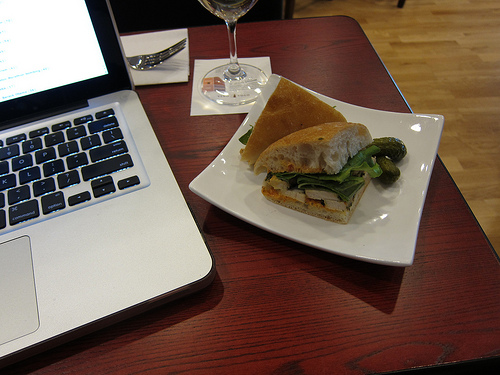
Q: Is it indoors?
A: Yes, it is indoors.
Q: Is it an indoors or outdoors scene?
A: It is indoors.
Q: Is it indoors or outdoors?
A: It is indoors.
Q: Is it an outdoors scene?
A: No, it is indoors.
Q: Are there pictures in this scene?
A: No, there are no pictures.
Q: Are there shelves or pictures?
A: No, there are no pictures or shelves.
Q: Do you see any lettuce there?
A: Yes, there is lettuce.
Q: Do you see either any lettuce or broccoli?
A: Yes, there is lettuce.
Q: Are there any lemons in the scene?
A: No, there are no lemons.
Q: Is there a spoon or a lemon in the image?
A: No, there are no lemons or spoons.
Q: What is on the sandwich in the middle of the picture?
A: The lettuce is on the sandwich.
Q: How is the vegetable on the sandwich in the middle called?
A: The vegetable is lettuce.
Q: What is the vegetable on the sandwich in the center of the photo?
A: The vegetable is lettuce.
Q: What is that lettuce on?
A: The lettuce is on the sandwich.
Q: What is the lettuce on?
A: The lettuce is on the sandwich.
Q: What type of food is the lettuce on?
A: The lettuce is on the sandwich.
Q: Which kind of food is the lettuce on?
A: The lettuce is on the sandwich.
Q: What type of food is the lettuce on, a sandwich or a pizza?
A: The lettuce is on a sandwich.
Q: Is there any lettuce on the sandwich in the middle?
A: Yes, there is lettuce on the sandwich.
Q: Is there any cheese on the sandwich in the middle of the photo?
A: No, there is lettuce on the sandwich.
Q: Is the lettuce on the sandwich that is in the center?
A: Yes, the lettuce is on the sandwich.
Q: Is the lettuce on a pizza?
A: No, the lettuce is on the sandwich.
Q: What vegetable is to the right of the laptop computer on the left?
A: The vegetable is lettuce.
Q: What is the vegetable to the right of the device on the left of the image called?
A: The vegetable is lettuce.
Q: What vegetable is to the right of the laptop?
A: The vegetable is lettuce.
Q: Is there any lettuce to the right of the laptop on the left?
A: Yes, there is lettuce to the right of the laptop.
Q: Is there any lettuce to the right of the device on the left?
A: Yes, there is lettuce to the right of the laptop.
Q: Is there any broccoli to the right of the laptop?
A: No, there is lettuce to the right of the laptop.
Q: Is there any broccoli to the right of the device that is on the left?
A: No, there is lettuce to the right of the laptop.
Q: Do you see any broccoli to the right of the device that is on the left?
A: No, there is lettuce to the right of the laptop.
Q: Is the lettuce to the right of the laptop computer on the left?
A: Yes, the lettuce is to the right of the laptop.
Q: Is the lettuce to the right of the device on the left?
A: Yes, the lettuce is to the right of the laptop.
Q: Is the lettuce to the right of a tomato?
A: No, the lettuce is to the right of the laptop.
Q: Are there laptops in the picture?
A: Yes, there is a laptop.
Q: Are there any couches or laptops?
A: Yes, there is a laptop.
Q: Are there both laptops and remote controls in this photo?
A: No, there is a laptop but no remote controls.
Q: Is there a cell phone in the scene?
A: No, there are no cell phones.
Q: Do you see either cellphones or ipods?
A: No, there are no cellphones or ipods.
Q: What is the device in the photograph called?
A: The device is a laptop.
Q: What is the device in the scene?
A: The device is a laptop.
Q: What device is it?
A: The device is a laptop.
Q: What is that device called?
A: This is a laptop.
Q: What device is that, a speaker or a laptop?
A: This is a laptop.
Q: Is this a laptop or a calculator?
A: This is a laptop.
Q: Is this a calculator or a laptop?
A: This is a laptop.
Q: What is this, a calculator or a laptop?
A: This is a laptop.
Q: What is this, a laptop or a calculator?
A: This is a laptop.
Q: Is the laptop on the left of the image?
A: Yes, the laptop is on the left of the image.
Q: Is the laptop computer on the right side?
A: No, the laptop computer is on the left of the image.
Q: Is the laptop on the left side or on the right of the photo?
A: The laptop is on the left of the image.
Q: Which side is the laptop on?
A: The laptop is on the left of the image.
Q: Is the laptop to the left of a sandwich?
A: Yes, the laptop is to the left of a sandwich.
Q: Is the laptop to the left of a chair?
A: No, the laptop is to the left of a sandwich.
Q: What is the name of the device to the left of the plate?
A: The device is a laptop.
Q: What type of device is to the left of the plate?
A: The device is a laptop.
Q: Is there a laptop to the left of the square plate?
A: Yes, there is a laptop to the left of the plate.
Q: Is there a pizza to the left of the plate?
A: No, there is a laptop to the left of the plate.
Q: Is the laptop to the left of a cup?
A: No, the laptop is to the left of the plate.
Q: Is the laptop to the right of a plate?
A: No, the laptop is to the left of a plate.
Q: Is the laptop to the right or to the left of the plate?
A: The laptop is to the left of the plate.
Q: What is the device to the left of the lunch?
A: The device is a laptop.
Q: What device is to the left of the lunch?
A: The device is a laptop.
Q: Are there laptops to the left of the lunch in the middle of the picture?
A: Yes, there is a laptop to the left of the lunch.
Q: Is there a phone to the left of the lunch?
A: No, there is a laptop to the left of the lunch.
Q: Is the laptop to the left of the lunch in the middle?
A: Yes, the laptop is to the left of the lunch.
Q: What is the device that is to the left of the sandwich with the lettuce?
A: The device is a laptop.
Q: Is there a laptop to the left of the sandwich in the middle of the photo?
A: Yes, there is a laptop to the left of the sandwich.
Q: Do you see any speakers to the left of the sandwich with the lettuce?
A: No, there is a laptop to the left of the sandwich.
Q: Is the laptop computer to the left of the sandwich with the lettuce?
A: Yes, the laptop computer is to the left of the sandwich.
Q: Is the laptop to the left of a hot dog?
A: No, the laptop is to the left of the sandwich.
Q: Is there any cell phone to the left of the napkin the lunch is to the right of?
A: No, there is a laptop to the left of the napkin.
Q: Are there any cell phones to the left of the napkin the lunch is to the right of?
A: No, there is a laptop to the left of the napkin.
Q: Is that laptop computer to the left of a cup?
A: No, the laptop computer is to the left of the napkin.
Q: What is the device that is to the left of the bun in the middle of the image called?
A: The device is a laptop.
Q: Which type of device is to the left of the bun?
A: The device is a laptop.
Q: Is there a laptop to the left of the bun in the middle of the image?
A: Yes, there is a laptop to the left of the bun.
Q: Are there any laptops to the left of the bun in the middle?
A: Yes, there is a laptop to the left of the bun.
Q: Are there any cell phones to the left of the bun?
A: No, there is a laptop to the left of the bun.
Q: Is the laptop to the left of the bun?
A: Yes, the laptop is to the left of the bun.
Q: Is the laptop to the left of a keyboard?
A: No, the laptop is to the left of the bun.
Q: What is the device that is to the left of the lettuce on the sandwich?
A: The device is a laptop.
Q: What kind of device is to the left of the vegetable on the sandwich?
A: The device is a laptop.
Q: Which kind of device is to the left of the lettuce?
A: The device is a laptop.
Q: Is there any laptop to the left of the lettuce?
A: Yes, there is a laptop to the left of the lettuce.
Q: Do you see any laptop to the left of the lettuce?
A: Yes, there is a laptop to the left of the lettuce.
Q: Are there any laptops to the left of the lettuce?
A: Yes, there is a laptop to the left of the lettuce.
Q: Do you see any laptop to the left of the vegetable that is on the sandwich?
A: Yes, there is a laptop to the left of the lettuce.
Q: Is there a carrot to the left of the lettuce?
A: No, there is a laptop to the left of the lettuce.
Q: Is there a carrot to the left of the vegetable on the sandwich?
A: No, there is a laptop to the left of the lettuce.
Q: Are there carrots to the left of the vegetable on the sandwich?
A: No, there is a laptop to the left of the lettuce.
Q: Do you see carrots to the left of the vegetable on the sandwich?
A: No, there is a laptop to the left of the lettuce.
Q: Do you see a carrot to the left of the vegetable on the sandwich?
A: No, there is a laptop to the left of the lettuce.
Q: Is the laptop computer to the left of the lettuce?
A: Yes, the laptop computer is to the left of the lettuce.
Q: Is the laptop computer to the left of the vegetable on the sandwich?
A: Yes, the laptop computer is to the left of the lettuce.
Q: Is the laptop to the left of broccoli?
A: No, the laptop is to the left of the lettuce.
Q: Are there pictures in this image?
A: No, there are no pictures.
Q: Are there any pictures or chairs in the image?
A: No, there are no pictures or chairs.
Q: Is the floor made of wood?
A: Yes, the floor is made of wood.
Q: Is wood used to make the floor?
A: Yes, the floor is made of wood.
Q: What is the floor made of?
A: The floor is made of wood.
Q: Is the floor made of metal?
A: No, the floor is made of wood.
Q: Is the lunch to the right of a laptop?
A: Yes, the lunch is to the right of a laptop.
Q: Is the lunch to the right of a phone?
A: No, the lunch is to the right of a laptop.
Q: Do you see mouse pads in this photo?
A: Yes, there is a mouse pad.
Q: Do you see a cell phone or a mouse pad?
A: Yes, there is a mouse pad.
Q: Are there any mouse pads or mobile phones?
A: Yes, there is a mouse pad.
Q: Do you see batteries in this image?
A: No, there are no batteries.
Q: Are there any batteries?
A: No, there are no batteries.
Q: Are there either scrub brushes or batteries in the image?
A: No, there are no batteries or scrub brushes.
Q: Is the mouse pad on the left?
A: Yes, the mouse pad is on the left of the image.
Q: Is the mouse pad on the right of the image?
A: No, the mouse pad is on the left of the image.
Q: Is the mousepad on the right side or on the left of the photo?
A: The mousepad is on the left of the image.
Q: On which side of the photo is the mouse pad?
A: The mouse pad is on the left of the image.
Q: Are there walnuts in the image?
A: No, there are no walnuts.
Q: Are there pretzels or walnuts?
A: No, there are no walnuts or pretzels.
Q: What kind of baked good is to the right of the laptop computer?
A: The food is a bun.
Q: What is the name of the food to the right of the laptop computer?
A: The food is a bun.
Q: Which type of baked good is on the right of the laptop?
A: The food is a bun.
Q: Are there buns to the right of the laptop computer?
A: Yes, there is a bun to the right of the laptop computer.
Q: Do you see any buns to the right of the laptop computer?
A: Yes, there is a bun to the right of the laptop computer.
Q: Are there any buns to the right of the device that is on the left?
A: Yes, there is a bun to the right of the laptop computer.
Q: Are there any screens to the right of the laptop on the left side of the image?
A: No, there is a bun to the right of the laptop computer.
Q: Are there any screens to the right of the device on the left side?
A: No, there is a bun to the right of the laptop computer.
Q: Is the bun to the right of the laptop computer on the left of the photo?
A: Yes, the bun is to the right of the laptop.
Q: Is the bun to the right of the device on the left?
A: Yes, the bun is to the right of the laptop.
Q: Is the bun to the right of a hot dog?
A: No, the bun is to the right of the laptop.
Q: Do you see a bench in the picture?
A: No, there are no benches.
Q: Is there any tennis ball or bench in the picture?
A: No, there are no benches or tennis balls.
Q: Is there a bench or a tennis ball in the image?
A: No, there are no benches or tennis balls.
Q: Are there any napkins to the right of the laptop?
A: Yes, there is a napkin to the right of the laptop.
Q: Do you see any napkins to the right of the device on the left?
A: Yes, there is a napkin to the right of the laptop.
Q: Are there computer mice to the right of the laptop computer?
A: No, there is a napkin to the right of the laptop computer.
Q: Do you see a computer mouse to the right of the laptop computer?
A: No, there is a napkin to the right of the laptop computer.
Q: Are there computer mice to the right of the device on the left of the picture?
A: No, there is a napkin to the right of the laptop computer.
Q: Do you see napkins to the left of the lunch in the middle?
A: Yes, there is a napkin to the left of the lunch.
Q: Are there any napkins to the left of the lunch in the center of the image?
A: Yes, there is a napkin to the left of the lunch.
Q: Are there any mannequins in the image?
A: No, there are no mannequins.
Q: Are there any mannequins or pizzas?
A: No, there are no mannequins or pizzas.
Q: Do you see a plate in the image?
A: Yes, there is a plate.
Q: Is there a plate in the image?
A: Yes, there is a plate.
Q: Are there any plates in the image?
A: Yes, there is a plate.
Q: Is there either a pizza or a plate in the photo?
A: Yes, there is a plate.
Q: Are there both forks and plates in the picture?
A: Yes, there are both a plate and a fork.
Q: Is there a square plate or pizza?
A: Yes, there is a square plate.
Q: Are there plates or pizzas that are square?
A: Yes, the plate is square.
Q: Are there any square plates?
A: Yes, there is a square plate.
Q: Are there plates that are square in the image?
A: Yes, there is a square plate.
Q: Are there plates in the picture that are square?
A: Yes, there is a plate that is square.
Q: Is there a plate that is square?
A: Yes, there is a plate that is square.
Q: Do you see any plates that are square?
A: Yes, there is a plate that is square.